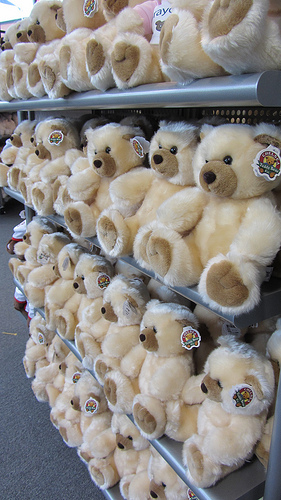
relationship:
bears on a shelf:
[2, 0, 279, 499] [1, 74, 275, 114]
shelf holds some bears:
[1, 74, 275, 114] [2, 0, 279, 499]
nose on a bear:
[203, 172, 219, 184] [143, 121, 277, 263]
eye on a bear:
[169, 143, 179, 159] [143, 121, 277, 263]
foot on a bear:
[199, 257, 263, 316] [143, 121, 277, 263]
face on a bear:
[146, 128, 194, 184] [143, 121, 277, 263]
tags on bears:
[176, 327, 254, 407] [2, 0, 279, 499]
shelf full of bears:
[1, 74, 275, 114] [2, 0, 279, 499]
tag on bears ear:
[252, 144, 281, 183] [252, 120, 280, 147]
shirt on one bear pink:
[129, 1, 158, 35] [134, 0, 155, 29]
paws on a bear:
[154, 193, 265, 268] [143, 121, 277, 263]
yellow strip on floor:
[3, 328, 18, 339] [1, 203, 120, 499]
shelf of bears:
[1, 74, 275, 114] [2, 0, 279, 499]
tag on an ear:
[252, 144, 281, 183] [252, 120, 280, 147]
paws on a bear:
[108, 177, 191, 233] [143, 121, 277, 263]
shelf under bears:
[1, 74, 275, 114] [2, 0, 279, 499]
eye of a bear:
[169, 143, 179, 159] [143, 121, 277, 263]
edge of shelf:
[255, 64, 280, 112] [1, 74, 275, 114]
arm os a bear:
[237, 195, 280, 266] [143, 121, 277, 263]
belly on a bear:
[188, 205, 241, 258] [143, 121, 277, 263]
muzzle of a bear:
[200, 161, 238, 200] [143, 121, 277, 263]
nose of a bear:
[203, 172, 219, 184] [143, 121, 277, 263]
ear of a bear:
[252, 120, 280, 147] [143, 121, 277, 263]